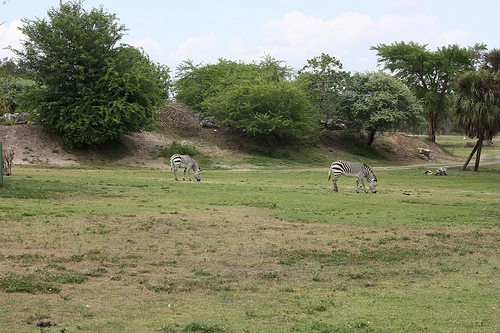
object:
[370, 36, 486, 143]
tree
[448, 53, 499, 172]
tree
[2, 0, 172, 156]
bush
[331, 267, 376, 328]
grass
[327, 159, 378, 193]
zebra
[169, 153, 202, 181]
zebra grazing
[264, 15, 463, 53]
clouds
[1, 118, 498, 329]
ground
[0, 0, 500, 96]
sky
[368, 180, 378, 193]
zebra head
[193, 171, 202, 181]
zebra head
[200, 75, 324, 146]
bush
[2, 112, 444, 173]
hill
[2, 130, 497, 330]
field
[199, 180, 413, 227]
grass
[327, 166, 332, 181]
tail